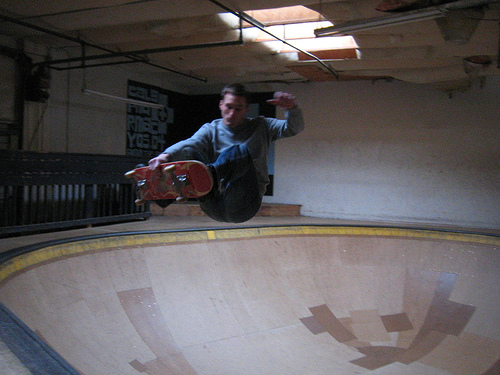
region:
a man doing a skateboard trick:
[115, 75, 309, 220]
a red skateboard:
[117, 158, 213, 210]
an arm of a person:
[266, 88, 306, 144]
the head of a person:
[217, 82, 255, 131]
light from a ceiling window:
[222, 7, 366, 68]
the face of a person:
[221, 99, 245, 128]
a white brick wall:
[348, 128, 427, 203]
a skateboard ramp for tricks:
[128, 220, 255, 362]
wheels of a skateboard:
[162, 161, 193, 208]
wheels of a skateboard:
[129, 163, 152, 213]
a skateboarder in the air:
[115, 75, 313, 237]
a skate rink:
[24, 30, 498, 345]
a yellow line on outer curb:
[6, 219, 498, 321]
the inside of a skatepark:
[6, 10, 498, 370]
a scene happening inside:
[11, 13, 488, 373]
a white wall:
[268, 81, 495, 243]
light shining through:
[212, 5, 367, 75]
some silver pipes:
[34, 12, 334, 77]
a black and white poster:
[122, 70, 174, 172]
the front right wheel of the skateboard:
[161, 162, 181, 175]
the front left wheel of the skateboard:
[173, 190, 188, 207]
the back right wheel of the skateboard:
[120, 166, 140, 180]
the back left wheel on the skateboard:
[130, 193, 145, 208]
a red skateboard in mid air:
[113, 154, 216, 216]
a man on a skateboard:
[120, 60, 315, 238]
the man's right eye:
[223, 101, 233, 111]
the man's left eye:
[232, 101, 244, 116]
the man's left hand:
[266, 84, 297, 114]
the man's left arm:
[259, 90, 309, 142]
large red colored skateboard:
[124, 160, 214, 202]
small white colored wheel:
[163, 163, 175, 172]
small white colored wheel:
[175, 194, 187, 202]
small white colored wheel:
[122, 168, 137, 179]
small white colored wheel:
[134, 196, 144, 203]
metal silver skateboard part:
[174, 175, 188, 183]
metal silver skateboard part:
[135, 179, 147, 190]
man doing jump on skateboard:
[144, 80, 304, 223]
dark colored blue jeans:
[184, 142, 262, 223]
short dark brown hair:
[219, 81, 251, 108]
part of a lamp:
[375, 278, 412, 292]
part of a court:
[247, 340, 267, 355]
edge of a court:
[319, 183, 374, 256]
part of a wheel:
[164, 191, 193, 214]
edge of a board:
[196, 178, 213, 210]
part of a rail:
[17, 190, 52, 211]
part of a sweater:
[258, 125, 265, 137]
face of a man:
[213, 93, 258, 130]